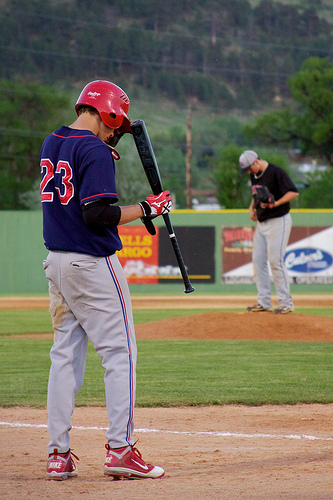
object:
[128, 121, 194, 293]
baseball bat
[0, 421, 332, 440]
line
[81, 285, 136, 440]
legs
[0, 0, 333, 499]
background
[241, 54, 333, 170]
tree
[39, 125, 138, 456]
uniform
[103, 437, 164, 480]
red sneakers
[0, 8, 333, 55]
power line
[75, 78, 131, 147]
helmet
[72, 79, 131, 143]
head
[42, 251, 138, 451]
pants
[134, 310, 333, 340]
dirt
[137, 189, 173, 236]
glove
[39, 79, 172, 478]
player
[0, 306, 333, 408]
grass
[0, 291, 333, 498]
ground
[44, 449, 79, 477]
shoe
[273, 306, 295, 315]
shoe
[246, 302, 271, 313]
shoe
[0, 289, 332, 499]
baseball field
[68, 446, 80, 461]
cleats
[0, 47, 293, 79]
metal wire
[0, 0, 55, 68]
air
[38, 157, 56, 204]
number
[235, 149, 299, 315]
baseball player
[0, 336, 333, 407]
patch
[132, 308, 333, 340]
mound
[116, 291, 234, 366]
part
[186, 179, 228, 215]
part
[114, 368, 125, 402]
gray